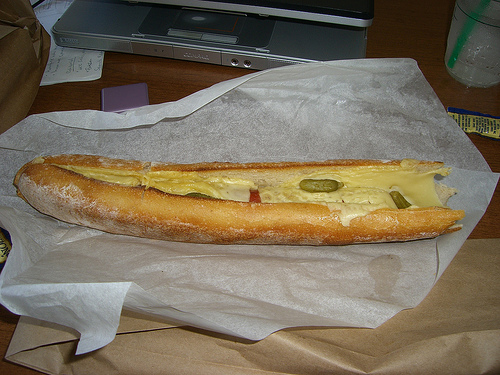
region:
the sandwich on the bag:
[18, 146, 463, 254]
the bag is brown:
[16, 241, 498, 373]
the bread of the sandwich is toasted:
[23, 143, 474, 234]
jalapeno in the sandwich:
[298, 177, 347, 194]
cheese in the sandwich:
[166, 177, 421, 213]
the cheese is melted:
[273, 176, 471, 220]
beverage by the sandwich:
[441, 2, 498, 90]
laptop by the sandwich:
[46, 2, 393, 74]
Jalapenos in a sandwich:
[187, 167, 419, 214]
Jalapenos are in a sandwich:
[180, 169, 418, 211]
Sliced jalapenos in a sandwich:
[179, 175, 419, 214]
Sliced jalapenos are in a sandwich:
[178, 170, 418, 211]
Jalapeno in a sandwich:
[290, 170, 342, 192]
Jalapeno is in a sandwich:
[290, 170, 346, 190]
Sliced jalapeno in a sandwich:
[295, 173, 354, 193]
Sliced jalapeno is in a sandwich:
[298, 176, 344, 195]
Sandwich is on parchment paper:
[1, 53, 495, 359]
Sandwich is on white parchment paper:
[0, 50, 497, 360]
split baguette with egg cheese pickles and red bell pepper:
[13, 152, 461, 243]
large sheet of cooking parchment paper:
[5, 57, 496, 352]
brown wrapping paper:
[10, 236, 497, 372]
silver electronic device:
[52, 0, 372, 72]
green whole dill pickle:
[298, 177, 341, 192]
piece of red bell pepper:
[246, 185, 257, 200]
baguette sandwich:
[10, 151, 460, 236]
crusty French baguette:
[12, 151, 462, 242]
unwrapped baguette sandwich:
[1, 58, 496, 373]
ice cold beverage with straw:
[445, 0, 498, 87]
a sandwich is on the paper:
[21, 152, 460, 243]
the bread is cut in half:
[24, 152, 454, 249]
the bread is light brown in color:
[13, 149, 463, 254]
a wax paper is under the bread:
[6, 63, 483, 334]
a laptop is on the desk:
[52, 4, 378, 81]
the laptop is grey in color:
[53, 3, 380, 77]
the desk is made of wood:
[0, 2, 494, 372]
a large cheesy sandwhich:
[36, 136, 450, 249]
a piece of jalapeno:
[302, 170, 357, 199]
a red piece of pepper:
[233, 188, 272, 200]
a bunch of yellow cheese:
[347, 174, 370, 207]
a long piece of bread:
[276, 201, 378, 246]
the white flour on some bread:
[258, 219, 283, 249]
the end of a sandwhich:
[28, 148, 85, 198]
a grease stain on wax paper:
[344, 247, 399, 304]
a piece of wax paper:
[166, 105, 243, 147]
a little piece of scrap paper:
[90, 74, 140, 115]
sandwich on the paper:
[14, 138, 497, 280]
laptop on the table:
[53, 10, 378, 76]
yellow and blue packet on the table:
[421, 104, 498, 139]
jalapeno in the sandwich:
[294, 173, 354, 195]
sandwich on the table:
[14, 135, 447, 254]